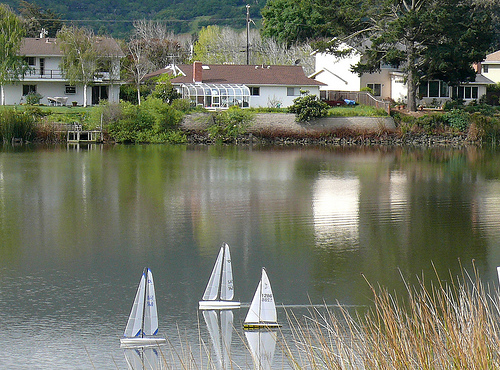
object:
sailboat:
[119, 265, 168, 344]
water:
[0, 143, 499, 243]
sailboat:
[197, 242, 241, 306]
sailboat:
[243, 266, 280, 328]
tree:
[261, 0, 500, 114]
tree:
[0, 0, 33, 106]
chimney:
[192, 61, 202, 84]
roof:
[126, 64, 330, 85]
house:
[127, 63, 329, 109]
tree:
[116, 21, 169, 106]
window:
[253, 87, 260, 95]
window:
[287, 87, 300, 96]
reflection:
[310, 170, 361, 251]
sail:
[118, 268, 166, 337]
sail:
[198, 242, 240, 301]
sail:
[242, 266, 282, 323]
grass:
[265, 257, 499, 370]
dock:
[0, 115, 105, 145]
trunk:
[406, 30, 417, 112]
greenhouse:
[172, 83, 250, 109]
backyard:
[185, 98, 387, 131]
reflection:
[198, 305, 237, 370]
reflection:
[244, 328, 279, 370]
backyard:
[0, 105, 151, 134]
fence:
[319, 90, 391, 116]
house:
[0, 33, 127, 106]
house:
[310, 27, 495, 108]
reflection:
[121, 344, 161, 370]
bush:
[107, 94, 187, 144]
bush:
[202, 103, 255, 147]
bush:
[0, 109, 33, 143]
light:
[245, 4, 251, 8]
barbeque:
[47, 96, 69, 107]